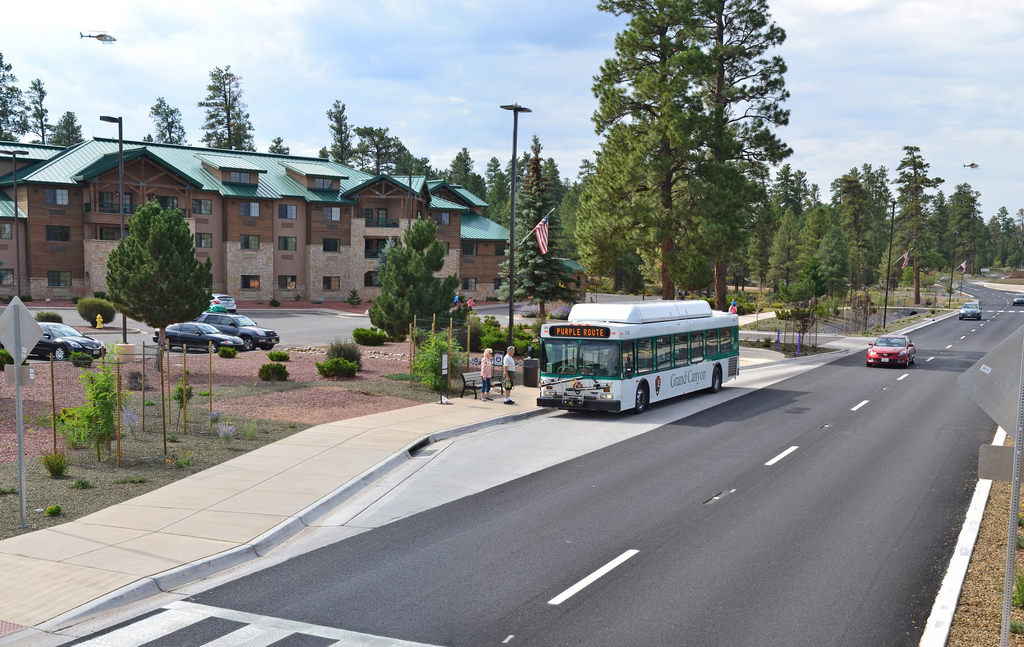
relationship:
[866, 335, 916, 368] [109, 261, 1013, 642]
red car on road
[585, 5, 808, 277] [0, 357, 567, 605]
trees near sidewalk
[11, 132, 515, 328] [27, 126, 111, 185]
building with roof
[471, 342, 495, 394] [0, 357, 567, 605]
woman standing on sidewalk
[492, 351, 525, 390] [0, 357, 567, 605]
man standing on sidewalk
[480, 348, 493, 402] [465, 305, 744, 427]
woman waiting at bus stop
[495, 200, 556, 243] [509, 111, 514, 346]
flag on side of post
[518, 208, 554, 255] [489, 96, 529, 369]
flag on pole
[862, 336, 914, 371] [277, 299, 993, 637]
red car on street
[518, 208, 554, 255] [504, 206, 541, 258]
flag on flagpole